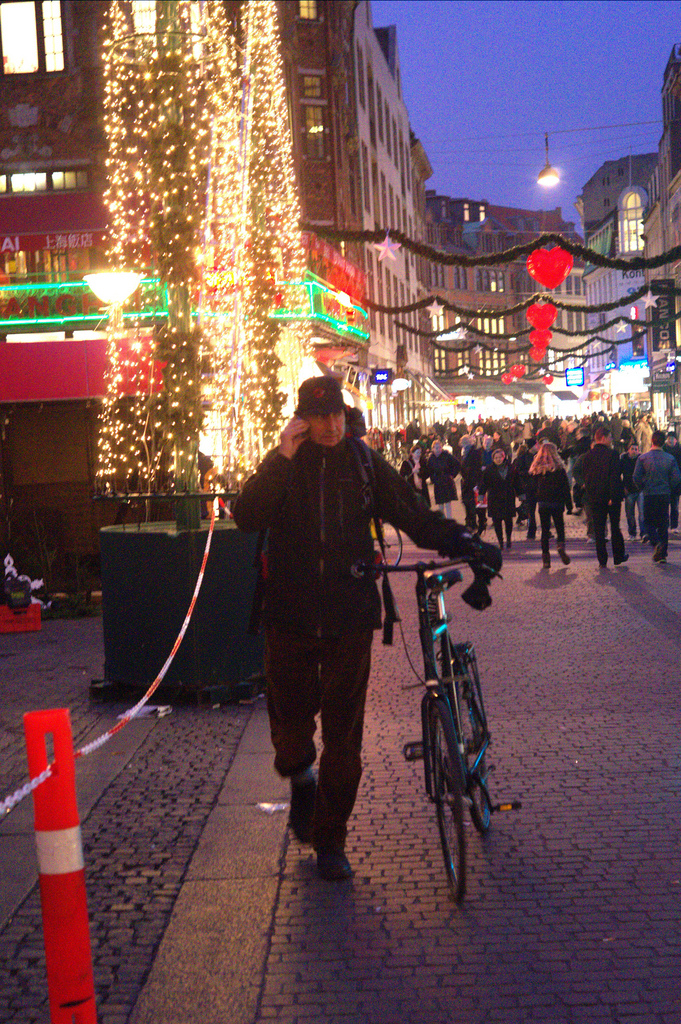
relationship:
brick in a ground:
[375, 868, 409, 893] [0, 501, 681, 1022]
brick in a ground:
[404, 906, 431, 931] [0, 501, 681, 1022]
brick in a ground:
[389, 938, 421, 947] [0, 501, 681, 1022]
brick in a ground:
[308, 958, 330, 975] [0, 501, 681, 1022]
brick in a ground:
[101, 924, 131, 949] [0, 501, 681, 1022]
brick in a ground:
[94, 944, 118, 963] [0, 501, 681, 1022]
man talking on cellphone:
[232, 375, 502, 879] [290, 422, 316, 440]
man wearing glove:
[232, 375, 502, 879] [458, 535, 517, 589]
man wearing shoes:
[232, 375, 502, 879] [282, 765, 359, 881]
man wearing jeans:
[232, 375, 502, 879] [539, 507, 565, 554]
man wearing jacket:
[232, 375, 502, 879] [233, 407, 465, 631]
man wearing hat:
[232, 375, 502, 879] [291, 376, 346, 415]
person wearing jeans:
[526, 443, 573, 569] [532, 495, 571, 570]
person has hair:
[526, 443, 573, 569] [527, 438, 561, 477]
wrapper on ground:
[254, 794, 283, 827] [0, 501, 678, 1021]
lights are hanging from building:
[101, 67, 340, 487] [0, 0, 428, 625]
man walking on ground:
[232, 375, 502, 879] [0, 501, 681, 1022]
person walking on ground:
[529, 442, 565, 570] [0, 501, 681, 1022]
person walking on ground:
[582, 435, 635, 577] [0, 501, 681, 1022]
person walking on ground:
[457, 435, 487, 534] [0, 501, 681, 1022]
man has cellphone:
[271, 394, 309, 444] [298, 413, 302, 437]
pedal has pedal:
[474, 769, 531, 844] [498, 800, 522, 811]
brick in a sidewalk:
[365, 845, 391, 868] [327, 712, 457, 988]